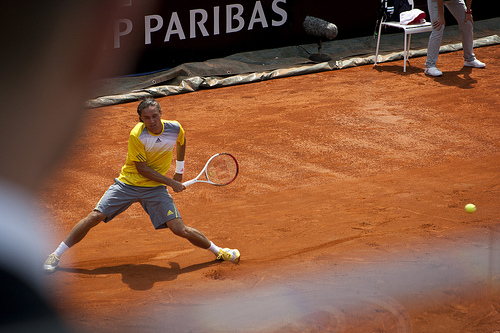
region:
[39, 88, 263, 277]
The man is holding a tennis racket.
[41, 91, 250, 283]
The man's legs are spread apart.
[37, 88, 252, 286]
The man is wearing gray shorts.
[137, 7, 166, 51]
The letter is white.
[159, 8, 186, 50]
The letter is white.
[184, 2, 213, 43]
The letter is white.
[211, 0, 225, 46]
The letter is white.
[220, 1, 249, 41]
The letter is white.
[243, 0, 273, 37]
The letter is white.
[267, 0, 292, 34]
The letter is white.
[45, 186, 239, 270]
legs stretched wide to reach a shot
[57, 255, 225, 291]
the shadow of the player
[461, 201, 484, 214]
ball sailing after being struck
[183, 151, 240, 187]
a red and white racquet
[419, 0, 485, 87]
part of a linesman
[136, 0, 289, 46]
part of the name of a French bank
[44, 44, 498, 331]
the brown clay court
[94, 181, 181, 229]
gray shorts on the competitor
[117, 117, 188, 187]
yellow shirt with gray and white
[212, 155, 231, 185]
logo of a sports manufacturer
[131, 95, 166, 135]
THATS A MANS HEAD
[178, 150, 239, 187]
THAT'S A TENNIS BRACKET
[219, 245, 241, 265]
THATS A TENNIS SHOE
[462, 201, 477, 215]
THATS A TENNIS BALL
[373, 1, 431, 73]
THATS A CHAIR BY THE MAN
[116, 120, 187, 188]
THAT'S HIS YELLOW SHIRT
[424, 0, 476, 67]
THOSE ARE GRAY PANTS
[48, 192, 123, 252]
THAT'S HIS RIGHT LEG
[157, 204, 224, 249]
THIS IS HIS LEFT LEG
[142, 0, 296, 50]
THIS IS A BILLBOARD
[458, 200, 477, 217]
Tennis ball in flight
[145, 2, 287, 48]
Paribas painted on courtside wall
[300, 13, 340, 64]
Microphone on edge of court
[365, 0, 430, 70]
Chair for tennis match official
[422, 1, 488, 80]
Match official with hands on knees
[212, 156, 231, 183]
W on tennis racket webbing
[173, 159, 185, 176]
Sweatband on players wrist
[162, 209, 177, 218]
Adidas business logo on shorts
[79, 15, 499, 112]
Protective court tarp rolled up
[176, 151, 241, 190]
White tennis racket made by Wilson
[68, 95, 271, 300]
Man on a tennis court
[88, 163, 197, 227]
man wearing gray pants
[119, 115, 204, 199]
man wearing a yellow and gray shirt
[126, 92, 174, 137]
man with blonde hair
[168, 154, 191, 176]
man wearing a white wristband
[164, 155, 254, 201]
man holding a tennis racket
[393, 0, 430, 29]
towel on the bench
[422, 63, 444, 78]
man wearing white sneakers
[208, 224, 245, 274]
man wearing yellow and white sneakers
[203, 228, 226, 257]
man wearing white socks